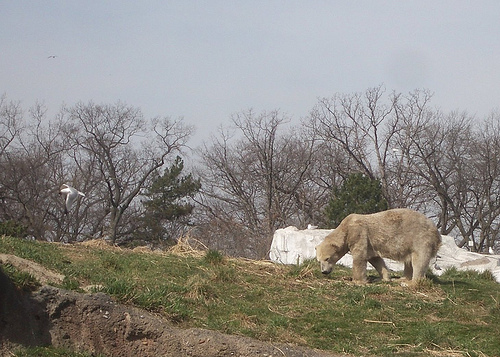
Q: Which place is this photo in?
A: It is at the field.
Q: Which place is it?
A: It is a field.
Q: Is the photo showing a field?
A: Yes, it is showing a field.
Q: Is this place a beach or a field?
A: It is a field.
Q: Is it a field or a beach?
A: It is a field.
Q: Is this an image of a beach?
A: No, the picture is showing a field.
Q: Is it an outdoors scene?
A: Yes, it is outdoors.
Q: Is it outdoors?
A: Yes, it is outdoors.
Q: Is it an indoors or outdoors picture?
A: It is outdoors.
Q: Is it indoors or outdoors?
A: It is outdoors.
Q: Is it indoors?
A: No, it is outdoors.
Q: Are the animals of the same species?
A: No, they are birds and bears.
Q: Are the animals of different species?
A: Yes, they are birds and bears.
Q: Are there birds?
A: Yes, there is a bird.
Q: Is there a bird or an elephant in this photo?
A: Yes, there is a bird.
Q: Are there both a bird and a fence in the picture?
A: No, there is a bird but no fences.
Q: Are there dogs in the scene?
A: No, there are no dogs.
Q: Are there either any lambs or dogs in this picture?
A: No, there are no dogs or lambs.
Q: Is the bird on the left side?
A: Yes, the bird is on the left of the image.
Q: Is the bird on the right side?
A: No, the bird is on the left of the image.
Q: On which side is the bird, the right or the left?
A: The bird is on the left of the image.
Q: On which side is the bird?
A: The bird is on the left of the image.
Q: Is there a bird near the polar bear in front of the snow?
A: Yes, there is a bird near the polar bear.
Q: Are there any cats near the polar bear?
A: No, there is a bird near the polar bear.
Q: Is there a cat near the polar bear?
A: No, there is a bird near the polar bear.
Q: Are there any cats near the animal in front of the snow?
A: No, there is a bird near the polar bear.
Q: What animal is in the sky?
A: The bird is in the sky.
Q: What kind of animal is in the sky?
A: The animal is a bird.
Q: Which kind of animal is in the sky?
A: The animal is a bird.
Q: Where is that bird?
A: The bird is in the sky.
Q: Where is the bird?
A: The bird is in the sky.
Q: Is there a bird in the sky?
A: Yes, there is a bird in the sky.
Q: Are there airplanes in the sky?
A: No, there is a bird in the sky.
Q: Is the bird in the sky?
A: Yes, the bird is in the sky.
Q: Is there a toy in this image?
A: No, there are no toys.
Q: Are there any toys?
A: No, there are no toys.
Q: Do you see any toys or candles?
A: No, there are no toys or candles.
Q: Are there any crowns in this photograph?
A: No, there are no crowns.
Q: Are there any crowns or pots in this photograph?
A: No, there are no crowns or pots.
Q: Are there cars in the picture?
A: No, there are no cars.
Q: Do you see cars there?
A: No, there are no cars.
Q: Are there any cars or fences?
A: No, there are no cars or fences.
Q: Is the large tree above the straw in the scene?
A: Yes, the tree is above the straw.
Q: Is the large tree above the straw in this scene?
A: Yes, the tree is above the straw.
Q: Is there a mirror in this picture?
A: No, there are no mirrors.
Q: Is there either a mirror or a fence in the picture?
A: No, there are no mirrors or fences.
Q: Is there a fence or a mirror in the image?
A: No, there are no mirrors or fences.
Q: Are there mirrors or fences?
A: No, there are no mirrors or fences.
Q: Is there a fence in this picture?
A: No, there are no fences.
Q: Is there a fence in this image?
A: No, there are no fences.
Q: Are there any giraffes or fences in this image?
A: No, there are no fences or giraffes.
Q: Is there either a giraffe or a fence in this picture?
A: No, there are no fences or giraffes.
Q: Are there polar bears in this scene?
A: Yes, there is a polar bear.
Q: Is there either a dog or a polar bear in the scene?
A: Yes, there is a polar bear.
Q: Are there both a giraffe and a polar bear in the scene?
A: No, there is a polar bear but no giraffes.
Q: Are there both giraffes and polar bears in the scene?
A: No, there is a polar bear but no giraffes.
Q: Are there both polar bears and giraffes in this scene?
A: No, there is a polar bear but no giraffes.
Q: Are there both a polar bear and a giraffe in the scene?
A: No, there is a polar bear but no giraffes.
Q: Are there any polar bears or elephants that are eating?
A: Yes, the polar bear is eating.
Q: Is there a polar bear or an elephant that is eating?
A: Yes, the polar bear is eating.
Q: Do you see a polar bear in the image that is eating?
A: Yes, there is a polar bear that is eating.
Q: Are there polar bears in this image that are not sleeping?
A: Yes, there is a polar bear that is eating.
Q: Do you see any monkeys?
A: No, there are no monkeys.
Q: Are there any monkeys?
A: No, there are no monkeys.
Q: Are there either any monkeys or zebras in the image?
A: No, there are no monkeys or zebras.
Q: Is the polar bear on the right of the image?
A: Yes, the polar bear is on the right of the image.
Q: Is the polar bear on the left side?
A: No, the polar bear is on the right of the image.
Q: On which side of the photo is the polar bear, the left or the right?
A: The polar bear is on the right of the image.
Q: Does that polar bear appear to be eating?
A: Yes, the polar bear is eating.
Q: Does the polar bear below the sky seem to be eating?
A: Yes, the polar bear is eating.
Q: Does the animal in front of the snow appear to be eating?
A: Yes, the polar bear is eating.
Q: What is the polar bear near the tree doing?
A: The polar bear is eating.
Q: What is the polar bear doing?
A: The polar bear is eating.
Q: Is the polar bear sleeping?
A: No, the polar bear is eating.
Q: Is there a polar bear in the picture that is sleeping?
A: No, there is a polar bear but it is eating.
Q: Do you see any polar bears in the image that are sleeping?
A: No, there is a polar bear but it is eating.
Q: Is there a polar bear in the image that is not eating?
A: No, there is a polar bear but it is eating.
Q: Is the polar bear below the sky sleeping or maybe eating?
A: The polar bear is eating.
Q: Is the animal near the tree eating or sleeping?
A: The polar bear is eating.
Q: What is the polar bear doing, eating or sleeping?
A: The polar bear is eating.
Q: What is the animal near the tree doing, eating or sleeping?
A: The polar bear is eating.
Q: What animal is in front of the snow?
A: The polar bear is in front of the snow.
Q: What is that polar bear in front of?
A: The polar bear is in front of the snow.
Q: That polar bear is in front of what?
A: The polar bear is in front of the snow.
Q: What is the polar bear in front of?
A: The polar bear is in front of the snow.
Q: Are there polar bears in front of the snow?
A: Yes, there is a polar bear in front of the snow.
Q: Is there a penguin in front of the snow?
A: No, there is a polar bear in front of the snow.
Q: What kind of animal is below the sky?
A: The animal is a polar bear.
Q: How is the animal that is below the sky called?
A: The animal is a polar bear.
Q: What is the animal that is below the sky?
A: The animal is a polar bear.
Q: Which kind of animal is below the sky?
A: The animal is a polar bear.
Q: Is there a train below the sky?
A: No, there is a polar bear below the sky.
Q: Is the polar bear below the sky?
A: Yes, the polar bear is below the sky.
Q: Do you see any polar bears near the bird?
A: Yes, there is a polar bear near the bird.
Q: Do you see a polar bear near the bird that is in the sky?
A: Yes, there is a polar bear near the bird.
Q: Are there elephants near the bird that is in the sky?
A: No, there is a polar bear near the bird.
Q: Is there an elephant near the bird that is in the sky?
A: No, there is a polar bear near the bird.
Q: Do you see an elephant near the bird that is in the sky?
A: No, there is a polar bear near the bird.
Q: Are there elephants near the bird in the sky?
A: No, there is a polar bear near the bird.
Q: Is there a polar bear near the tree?
A: Yes, there is a polar bear near the tree.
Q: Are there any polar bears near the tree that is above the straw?
A: Yes, there is a polar bear near the tree.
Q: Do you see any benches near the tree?
A: No, there is a polar bear near the tree.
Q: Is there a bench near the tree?
A: No, there is a polar bear near the tree.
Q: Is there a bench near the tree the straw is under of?
A: No, there is a polar bear near the tree.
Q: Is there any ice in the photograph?
A: Yes, there is ice.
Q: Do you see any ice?
A: Yes, there is ice.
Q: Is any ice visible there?
A: Yes, there is ice.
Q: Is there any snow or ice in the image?
A: Yes, there is ice.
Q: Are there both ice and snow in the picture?
A: Yes, there are both ice and snow.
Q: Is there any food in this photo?
A: No, there is no food.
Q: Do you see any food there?
A: No, there is no food.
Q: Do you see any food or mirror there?
A: No, there are no food or mirrors.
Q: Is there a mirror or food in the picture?
A: No, there are no food or mirrors.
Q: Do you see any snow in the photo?
A: Yes, there is snow.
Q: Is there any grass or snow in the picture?
A: Yes, there is snow.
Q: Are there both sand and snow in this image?
A: No, there is snow but no sand.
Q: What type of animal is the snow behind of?
A: The snow is behind the polar bear.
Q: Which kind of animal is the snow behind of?
A: The snow is behind the polar bear.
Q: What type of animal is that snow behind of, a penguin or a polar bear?
A: The snow is behind a polar bear.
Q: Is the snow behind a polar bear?
A: Yes, the snow is behind a polar bear.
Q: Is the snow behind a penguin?
A: No, the snow is behind a polar bear.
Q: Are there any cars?
A: No, there are no cars.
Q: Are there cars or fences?
A: No, there are no cars or fences.